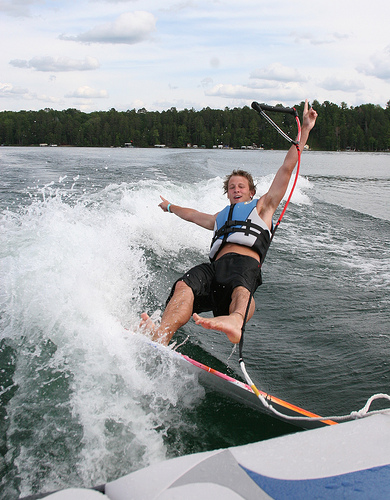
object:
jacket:
[208, 198, 273, 262]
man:
[140, 98, 318, 348]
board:
[175, 351, 339, 426]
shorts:
[165, 251, 264, 316]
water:
[17, 165, 151, 385]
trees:
[25, 107, 236, 144]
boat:
[36, 412, 389, 500]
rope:
[232, 356, 389, 420]